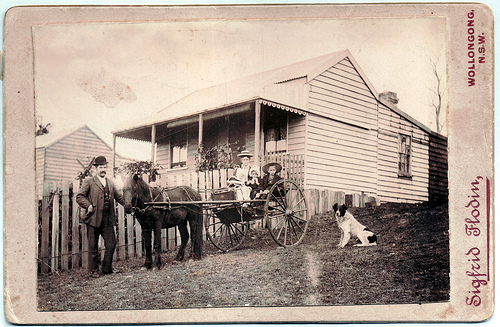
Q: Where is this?
A: This is at the yard.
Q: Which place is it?
A: It is a yard.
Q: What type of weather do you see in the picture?
A: It is cloudy.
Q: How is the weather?
A: It is cloudy.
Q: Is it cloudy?
A: Yes, it is cloudy.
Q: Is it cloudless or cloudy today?
A: It is cloudy.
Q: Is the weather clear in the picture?
A: No, it is cloudy.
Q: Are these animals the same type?
A: No, they are horses and dogs.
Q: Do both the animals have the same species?
A: No, they are horses and dogs.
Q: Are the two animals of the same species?
A: No, they are horses and dogs.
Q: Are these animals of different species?
A: Yes, they are horses and dogs.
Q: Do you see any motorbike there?
A: No, there are no motorcycles.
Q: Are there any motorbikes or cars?
A: No, there are no motorbikes or cars.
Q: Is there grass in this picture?
A: Yes, there is grass.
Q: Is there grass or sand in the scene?
A: Yes, there is grass.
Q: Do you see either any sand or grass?
A: Yes, there is grass.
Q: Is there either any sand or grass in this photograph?
A: Yes, there is grass.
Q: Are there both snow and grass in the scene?
A: No, there is grass but no snow.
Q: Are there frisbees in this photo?
A: No, there are no frisbees.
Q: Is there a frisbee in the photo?
A: No, there are no frisbees.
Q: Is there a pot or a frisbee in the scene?
A: No, there are no frisbees or pots.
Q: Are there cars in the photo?
A: No, there are no cars.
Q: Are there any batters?
A: No, there are no batters.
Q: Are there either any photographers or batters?
A: No, there are no batters or photographers.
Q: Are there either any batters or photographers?
A: No, there are no batters or photographers.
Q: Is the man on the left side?
A: Yes, the man is on the left of the image.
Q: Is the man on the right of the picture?
A: No, the man is on the left of the image.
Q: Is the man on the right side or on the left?
A: The man is on the left of the image.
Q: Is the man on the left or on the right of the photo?
A: The man is on the left of the image.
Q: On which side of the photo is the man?
A: The man is on the left of the image.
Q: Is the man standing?
A: Yes, the man is standing.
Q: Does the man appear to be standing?
A: Yes, the man is standing.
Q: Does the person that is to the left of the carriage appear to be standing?
A: Yes, the man is standing.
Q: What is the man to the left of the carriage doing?
A: The man is standing.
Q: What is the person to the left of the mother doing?
A: The man is standing.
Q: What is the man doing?
A: The man is standing.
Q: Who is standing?
A: The man is standing.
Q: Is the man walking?
A: No, the man is standing.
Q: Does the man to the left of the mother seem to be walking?
A: No, the man is standing.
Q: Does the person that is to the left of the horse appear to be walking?
A: No, the man is standing.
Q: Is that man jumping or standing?
A: The man is standing.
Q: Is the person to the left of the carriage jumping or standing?
A: The man is standing.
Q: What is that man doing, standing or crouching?
A: The man is standing.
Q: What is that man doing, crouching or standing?
A: The man is standing.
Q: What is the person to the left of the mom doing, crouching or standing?
A: The man is standing.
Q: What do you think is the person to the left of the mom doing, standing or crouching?
A: The man is standing.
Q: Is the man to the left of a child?
A: Yes, the man is to the left of a child.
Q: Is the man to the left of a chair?
A: No, the man is to the left of a child.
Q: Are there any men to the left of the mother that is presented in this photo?
A: Yes, there is a man to the left of the mother.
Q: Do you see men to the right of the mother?
A: No, the man is to the left of the mother.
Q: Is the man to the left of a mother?
A: Yes, the man is to the left of a mother.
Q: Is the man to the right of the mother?
A: No, the man is to the left of the mother.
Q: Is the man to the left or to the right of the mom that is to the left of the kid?
A: The man is to the left of the mother.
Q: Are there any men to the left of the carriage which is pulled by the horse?
A: Yes, there is a man to the left of the carriage.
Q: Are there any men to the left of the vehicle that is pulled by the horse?
A: Yes, there is a man to the left of the carriage.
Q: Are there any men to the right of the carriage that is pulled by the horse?
A: No, the man is to the left of the carriage.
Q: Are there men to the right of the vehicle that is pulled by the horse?
A: No, the man is to the left of the carriage.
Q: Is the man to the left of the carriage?
A: Yes, the man is to the left of the carriage.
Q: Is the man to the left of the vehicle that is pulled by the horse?
A: Yes, the man is to the left of the carriage.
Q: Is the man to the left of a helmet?
A: No, the man is to the left of the carriage.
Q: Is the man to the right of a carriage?
A: No, the man is to the left of a carriage.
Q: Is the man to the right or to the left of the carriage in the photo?
A: The man is to the left of the carriage.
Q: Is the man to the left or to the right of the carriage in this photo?
A: The man is to the left of the carriage.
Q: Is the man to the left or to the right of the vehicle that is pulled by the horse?
A: The man is to the left of the carriage.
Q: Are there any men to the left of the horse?
A: Yes, there is a man to the left of the horse.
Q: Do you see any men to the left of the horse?
A: Yes, there is a man to the left of the horse.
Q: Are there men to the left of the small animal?
A: Yes, there is a man to the left of the horse.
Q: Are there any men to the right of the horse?
A: No, the man is to the left of the horse.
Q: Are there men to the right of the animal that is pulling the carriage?
A: No, the man is to the left of the horse.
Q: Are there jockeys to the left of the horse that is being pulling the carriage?
A: No, there is a man to the left of the horse.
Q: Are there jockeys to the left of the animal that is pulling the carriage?
A: No, there is a man to the left of the horse.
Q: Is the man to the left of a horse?
A: Yes, the man is to the left of a horse.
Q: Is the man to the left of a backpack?
A: No, the man is to the left of a horse.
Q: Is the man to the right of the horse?
A: No, the man is to the left of the horse.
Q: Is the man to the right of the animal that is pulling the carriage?
A: No, the man is to the left of the horse.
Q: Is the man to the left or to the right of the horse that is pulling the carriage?
A: The man is to the left of the horse.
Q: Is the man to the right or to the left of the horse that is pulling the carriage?
A: The man is to the left of the horse.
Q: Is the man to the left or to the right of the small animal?
A: The man is to the left of the horse.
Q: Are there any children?
A: Yes, there is a child.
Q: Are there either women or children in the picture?
A: Yes, there is a child.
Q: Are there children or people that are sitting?
A: Yes, the child is sitting.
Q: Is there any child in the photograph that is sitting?
A: Yes, there is a child that is sitting.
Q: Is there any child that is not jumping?
A: Yes, there is a child that is sitting.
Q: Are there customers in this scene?
A: No, there are no customers.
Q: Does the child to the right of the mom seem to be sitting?
A: Yes, the child is sitting.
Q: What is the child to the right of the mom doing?
A: The child is sitting.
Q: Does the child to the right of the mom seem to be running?
A: No, the kid is sitting.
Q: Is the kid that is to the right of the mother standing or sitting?
A: The kid is sitting.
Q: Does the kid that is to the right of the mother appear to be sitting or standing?
A: The kid is sitting.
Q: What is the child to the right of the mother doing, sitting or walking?
A: The child is sitting.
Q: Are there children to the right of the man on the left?
A: Yes, there is a child to the right of the man.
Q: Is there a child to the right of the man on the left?
A: Yes, there is a child to the right of the man.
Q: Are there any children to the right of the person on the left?
A: Yes, there is a child to the right of the man.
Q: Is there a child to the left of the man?
A: No, the child is to the right of the man.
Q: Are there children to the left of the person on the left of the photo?
A: No, the child is to the right of the man.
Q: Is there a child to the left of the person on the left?
A: No, the child is to the right of the man.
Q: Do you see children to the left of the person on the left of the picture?
A: No, the child is to the right of the man.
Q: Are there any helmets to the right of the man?
A: No, there is a child to the right of the man.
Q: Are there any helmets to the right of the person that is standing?
A: No, there is a child to the right of the man.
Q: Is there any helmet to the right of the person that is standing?
A: No, there is a child to the right of the man.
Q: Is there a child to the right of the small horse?
A: Yes, there is a child to the right of the horse.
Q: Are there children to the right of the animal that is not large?
A: Yes, there is a child to the right of the horse.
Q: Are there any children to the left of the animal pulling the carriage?
A: No, the child is to the right of the horse.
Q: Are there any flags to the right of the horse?
A: No, there is a child to the right of the horse.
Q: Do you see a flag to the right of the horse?
A: No, there is a child to the right of the horse.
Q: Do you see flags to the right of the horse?
A: No, there is a child to the right of the horse.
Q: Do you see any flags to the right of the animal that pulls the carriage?
A: No, there is a child to the right of the horse.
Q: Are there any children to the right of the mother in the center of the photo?
A: Yes, there is a child to the right of the mom.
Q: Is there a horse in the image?
A: Yes, there is a horse.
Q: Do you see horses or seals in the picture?
A: Yes, there is a horse.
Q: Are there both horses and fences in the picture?
A: Yes, there are both a horse and a fence.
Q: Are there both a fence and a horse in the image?
A: Yes, there are both a horse and a fence.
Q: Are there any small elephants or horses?
A: Yes, there is a small horse.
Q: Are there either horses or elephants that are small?
A: Yes, the horse is small.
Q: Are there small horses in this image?
A: Yes, there is a small horse.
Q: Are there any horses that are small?
A: Yes, there is a horse that is small.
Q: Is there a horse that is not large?
A: Yes, there is a small horse.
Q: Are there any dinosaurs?
A: No, there are no dinosaurs.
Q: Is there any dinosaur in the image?
A: No, there are no dinosaurs.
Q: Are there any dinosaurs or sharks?
A: No, there are no dinosaurs or sharks.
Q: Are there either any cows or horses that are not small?
A: No, there is a horse but it is small.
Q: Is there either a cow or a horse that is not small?
A: No, there is a horse but it is small.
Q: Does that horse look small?
A: Yes, the horse is small.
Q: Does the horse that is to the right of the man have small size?
A: Yes, the horse is small.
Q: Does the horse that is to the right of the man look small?
A: Yes, the horse is small.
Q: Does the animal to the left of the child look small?
A: Yes, the horse is small.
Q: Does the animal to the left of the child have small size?
A: Yes, the horse is small.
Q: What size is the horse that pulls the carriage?
A: The horse is small.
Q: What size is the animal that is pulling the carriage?
A: The horse is small.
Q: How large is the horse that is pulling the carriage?
A: The horse is small.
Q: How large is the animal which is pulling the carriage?
A: The horse is small.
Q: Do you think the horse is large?
A: No, the horse is small.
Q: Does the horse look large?
A: No, the horse is small.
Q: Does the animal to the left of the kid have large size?
A: No, the horse is small.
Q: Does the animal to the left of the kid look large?
A: No, the horse is small.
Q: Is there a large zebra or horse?
A: No, there is a horse but it is small.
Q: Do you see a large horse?
A: No, there is a horse but it is small.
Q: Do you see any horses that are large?
A: No, there is a horse but it is small.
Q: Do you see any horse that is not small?
A: No, there is a horse but it is small.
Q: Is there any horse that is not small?
A: No, there is a horse but it is small.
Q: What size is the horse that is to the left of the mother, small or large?
A: The horse is small.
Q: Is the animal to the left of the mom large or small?
A: The horse is small.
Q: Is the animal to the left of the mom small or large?
A: The horse is small.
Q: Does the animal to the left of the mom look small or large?
A: The horse is small.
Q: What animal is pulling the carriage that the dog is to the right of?
A: The horse is pulling the carriage.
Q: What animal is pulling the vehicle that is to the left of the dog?
A: The horse is pulling the carriage.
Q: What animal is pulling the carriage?
A: The horse is pulling the carriage.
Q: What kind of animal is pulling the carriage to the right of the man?
A: The animal is a horse.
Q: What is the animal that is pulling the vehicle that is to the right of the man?
A: The animal is a horse.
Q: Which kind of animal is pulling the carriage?
A: The animal is a horse.